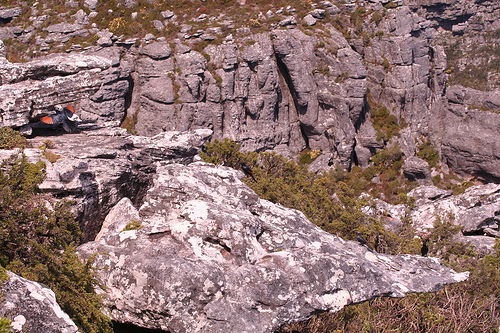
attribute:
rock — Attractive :
[1, 0, 499, 331]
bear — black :
[11, 105, 83, 137]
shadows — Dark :
[420, 2, 450, 13]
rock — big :
[55, 160, 471, 331]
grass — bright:
[3, 187, 110, 318]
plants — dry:
[141, 112, 493, 330]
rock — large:
[2, 45, 467, 129]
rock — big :
[130, 23, 376, 172]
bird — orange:
[28, 84, 155, 208]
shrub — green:
[4, 33, 103, 64]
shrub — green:
[231, 3, 291, 30]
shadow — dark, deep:
[273, 50, 303, 119]